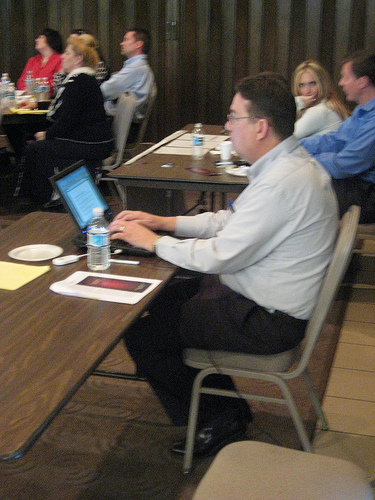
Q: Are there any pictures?
A: No, there are no pictures.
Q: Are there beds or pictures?
A: No, there are no pictures or beds.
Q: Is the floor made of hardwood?
A: Yes, the floor is made of hardwood.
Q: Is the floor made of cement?
A: No, the floor is made of hardwood.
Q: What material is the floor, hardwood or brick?
A: The floor is made of hardwood.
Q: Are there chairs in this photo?
A: Yes, there is a chair.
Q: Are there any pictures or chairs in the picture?
A: Yes, there is a chair.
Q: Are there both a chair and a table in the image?
A: Yes, there are both a chair and a table.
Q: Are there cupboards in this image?
A: No, there are no cupboards.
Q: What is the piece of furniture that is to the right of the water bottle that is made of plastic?
A: The piece of furniture is a chair.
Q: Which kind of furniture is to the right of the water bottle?
A: The piece of furniture is a chair.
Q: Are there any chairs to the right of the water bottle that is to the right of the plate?
A: Yes, there is a chair to the right of the water bottle.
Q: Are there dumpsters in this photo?
A: No, there are no dumpsters.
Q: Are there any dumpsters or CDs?
A: No, there are no dumpsters or cds.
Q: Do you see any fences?
A: No, there are no fences.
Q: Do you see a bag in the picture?
A: No, there are no bags.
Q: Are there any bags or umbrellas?
A: No, there are no bags or umbrellas.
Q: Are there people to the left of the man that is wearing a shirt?
A: Yes, there are people to the left of the man.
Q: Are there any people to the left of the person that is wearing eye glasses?
A: Yes, there are people to the left of the man.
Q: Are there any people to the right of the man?
A: No, the people are to the left of the man.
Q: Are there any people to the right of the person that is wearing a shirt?
A: No, the people are to the left of the man.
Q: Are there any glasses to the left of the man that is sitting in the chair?
A: No, there are people to the left of the man.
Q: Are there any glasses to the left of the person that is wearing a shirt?
A: No, there are people to the left of the man.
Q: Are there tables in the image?
A: Yes, there is a table.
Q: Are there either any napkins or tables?
A: Yes, there is a table.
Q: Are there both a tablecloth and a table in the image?
A: No, there is a table but no tablecloths.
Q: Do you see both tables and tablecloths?
A: No, there is a table but no tablecloths.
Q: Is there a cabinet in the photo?
A: No, there are no cabinets.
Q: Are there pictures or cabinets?
A: No, there are no cabinets or pictures.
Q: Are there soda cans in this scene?
A: No, there are no soda cans.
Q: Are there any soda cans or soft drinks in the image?
A: No, there are no soda cans or soft drinks.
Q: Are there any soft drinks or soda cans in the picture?
A: No, there are no soda cans or soft drinks.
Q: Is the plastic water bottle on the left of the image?
A: Yes, the water bottle is on the left of the image.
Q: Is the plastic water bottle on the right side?
A: No, the water bottle is on the left of the image.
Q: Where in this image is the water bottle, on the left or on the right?
A: The water bottle is on the left of the image.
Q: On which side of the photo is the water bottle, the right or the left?
A: The water bottle is on the left of the image.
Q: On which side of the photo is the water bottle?
A: The water bottle is on the left of the image.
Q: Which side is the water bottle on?
A: The water bottle is on the left of the image.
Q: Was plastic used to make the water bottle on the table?
A: Yes, the water bottle is made of plastic.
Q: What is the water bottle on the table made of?
A: The water bottle is made of plastic.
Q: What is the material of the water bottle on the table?
A: The water bottle is made of plastic.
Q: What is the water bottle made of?
A: The water bottle is made of plastic.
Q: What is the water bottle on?
A: The water bottle is on the table.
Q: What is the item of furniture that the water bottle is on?
A: The piece of furniture is a table.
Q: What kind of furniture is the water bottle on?
A: The water bottle is on the table.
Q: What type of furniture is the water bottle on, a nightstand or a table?
A: The water bottle is on a table.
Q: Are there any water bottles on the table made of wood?
A: Yes, there is a water bottle on the table.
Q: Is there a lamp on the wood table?
A: No, there is a water bottle on the table.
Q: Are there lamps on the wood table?
A: No, there is a water bottle on the table.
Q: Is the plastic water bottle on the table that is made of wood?
A: Yes, the water bottle is on the table.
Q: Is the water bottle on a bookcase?
A: No, the water bottle is on the table.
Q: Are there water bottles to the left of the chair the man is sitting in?
A: Yes, there is a water bottle to the left of the chair.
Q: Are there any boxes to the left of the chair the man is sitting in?
A: No, there is a water bottle to the left of the chair.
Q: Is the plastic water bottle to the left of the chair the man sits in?
A: Yes, the water bottle is to the left of the chair.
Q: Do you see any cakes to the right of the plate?
A: No, there is a water bottle to the right of the plate.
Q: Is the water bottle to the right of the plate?
A: Yes, the water bottle is to the right of the plate.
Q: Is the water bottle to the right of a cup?
A: No, the water bottle is to the right of the plate.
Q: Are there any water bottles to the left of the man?
A: Yes, there is a water bottle to the left of the man.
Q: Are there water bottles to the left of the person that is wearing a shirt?
A: Yes, there is a water bottle to the left of the man.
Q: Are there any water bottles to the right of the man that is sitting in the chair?
A: No, the water bottle is to the left of the man.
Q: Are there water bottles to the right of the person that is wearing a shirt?
A: No, the water bottle is to the left of the man.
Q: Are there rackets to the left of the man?
A: No, there is a water bottle to the left of the man.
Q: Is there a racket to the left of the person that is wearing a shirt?
A: No, there is a water bottle to the left of the man.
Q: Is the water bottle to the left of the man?
A: Yes, the water bottle is to the left of the man.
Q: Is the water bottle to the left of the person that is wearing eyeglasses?
A: Yes, the water bottle is to the left of the man.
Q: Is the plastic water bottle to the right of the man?
A: No, the water bottle is to the left of the man.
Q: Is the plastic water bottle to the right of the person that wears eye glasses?
A: No, the water bottle is to the left of the man.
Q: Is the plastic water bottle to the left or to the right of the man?
A: The water bottle is to the left of the man.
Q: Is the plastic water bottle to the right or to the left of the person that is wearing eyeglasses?
A: The water bottle is to the left of the man.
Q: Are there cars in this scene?
A: No, there are no cars.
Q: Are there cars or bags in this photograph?
A: No, there are no cars or bags.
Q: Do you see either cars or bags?
A: No, there are no cars or bags.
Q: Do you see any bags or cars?
A: No, there are no cars or bags.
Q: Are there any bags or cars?
A: No, there are no cars or bags.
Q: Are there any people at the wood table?
A: Yes, there are people at the table.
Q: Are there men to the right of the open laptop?
A: Yes, there is a man to the right of the laptop.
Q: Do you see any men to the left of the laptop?
A: No, the man is to the right of the laptop.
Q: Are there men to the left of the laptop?
A: No, the man is to the right of the laptop.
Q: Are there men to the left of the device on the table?
A: No, the man is to the right of the laptop.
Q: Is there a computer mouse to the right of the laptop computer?
A: No, there is a man to the right of the laptop computer.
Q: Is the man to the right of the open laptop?
A: Yes, the man is to the right of the laptop.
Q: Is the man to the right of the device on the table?
A: Yes, the man is to the right of the laptop.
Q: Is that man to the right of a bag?
A: No, the man is to the right of the laptop.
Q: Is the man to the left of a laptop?
A: No, the man is to the right of a laptop.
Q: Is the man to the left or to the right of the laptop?
A: The man is to the right of the laptop.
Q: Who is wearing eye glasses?
A: The man is wearing eye glasses.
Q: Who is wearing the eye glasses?
A: The man is wearing eye glasses.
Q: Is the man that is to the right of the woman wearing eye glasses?
A: Yes, the man is wearing eye glasses.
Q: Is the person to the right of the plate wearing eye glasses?
A: Yes, the man is wearing eye glasses.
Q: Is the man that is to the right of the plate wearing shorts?
A: No, the man is wearing eye glasses.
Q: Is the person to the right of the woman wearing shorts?
A: No, the man is wearing eye glasses.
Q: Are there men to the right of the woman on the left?
A: Yes, there is a man to the right of the woman.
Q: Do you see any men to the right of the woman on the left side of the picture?
A: Yes, there is a man to the right of the woman.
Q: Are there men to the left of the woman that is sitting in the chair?
A: No, the man is to the right of the woman.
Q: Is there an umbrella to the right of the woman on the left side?
A: No, there is a man to the right of the woman.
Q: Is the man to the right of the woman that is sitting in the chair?
A: Yes, the man is to the right of the woman.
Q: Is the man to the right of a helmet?
A: No, the man is to the right of the woman.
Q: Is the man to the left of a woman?
A: No, the man is to the right of a woman.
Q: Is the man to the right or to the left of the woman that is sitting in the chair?
A: The man is to the right of the woman.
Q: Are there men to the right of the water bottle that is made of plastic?
A: Yes, there is a man to the right of the water bottle.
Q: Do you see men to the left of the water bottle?
A: No, the man is to the right of the water bottle.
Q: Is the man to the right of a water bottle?
A: Yes, the man is to the right of a water bottle.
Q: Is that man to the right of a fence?
A: No, the man is to the right of a water bottle.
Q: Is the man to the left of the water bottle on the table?
A: No, the man is to the right of the water bottle.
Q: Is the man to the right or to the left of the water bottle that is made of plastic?
A: The man is to the right of the water bottle.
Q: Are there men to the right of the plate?
A: Yes, there is a man to the right of the plate.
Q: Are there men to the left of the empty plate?
A: No, the man is to the right of the plate.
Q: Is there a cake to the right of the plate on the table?
A: No, there is a man to the right of the plate.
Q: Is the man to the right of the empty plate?
A: Yes, the man is to the right of the plate.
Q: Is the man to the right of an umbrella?
A: No, the man is to the right of the plate.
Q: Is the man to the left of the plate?
A: No, the man is to the right of the plate.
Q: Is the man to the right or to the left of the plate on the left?
A: The man is to the right of the plate.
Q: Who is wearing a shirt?
A: The man is wearing a shirt.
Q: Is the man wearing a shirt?
A: Yes, the man is wearing a shirt.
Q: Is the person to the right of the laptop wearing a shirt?
A: Yes, the man is wearing a shirt.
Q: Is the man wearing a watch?
A: No, the man is wearing a shirt.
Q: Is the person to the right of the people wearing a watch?
A: No, the man is wearing a shirt.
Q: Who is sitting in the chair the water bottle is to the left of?
A: The man is sitting in the chair.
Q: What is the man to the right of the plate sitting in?
A: The man is sitting in the chair.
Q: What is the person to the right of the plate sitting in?
A: The man is sitting in the chair.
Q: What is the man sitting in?
A: The man is sitting in the chair.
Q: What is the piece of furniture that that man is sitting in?
A: The piece of furniture is a chair.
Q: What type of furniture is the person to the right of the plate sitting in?
A: The man is sitting in the chair.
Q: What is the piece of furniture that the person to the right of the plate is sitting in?
A: The piece of furniture is a chair.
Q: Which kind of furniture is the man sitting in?
A: The man is sitting in the chair.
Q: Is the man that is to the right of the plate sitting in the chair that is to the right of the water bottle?
A: Yes, the man is sitting in the chair.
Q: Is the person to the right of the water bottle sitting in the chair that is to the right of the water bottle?
A: Yes, the man is sitting in the chair.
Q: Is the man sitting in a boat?
A: No, the man is sitting in the chair.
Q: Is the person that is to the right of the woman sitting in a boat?
A: No, the man is sitting in the chair.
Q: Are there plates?
A: Yes, there is a plate.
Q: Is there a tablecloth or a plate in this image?
A: Yes, there is a plate.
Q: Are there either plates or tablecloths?
A: Yes, there is a plate.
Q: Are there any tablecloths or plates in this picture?
A: Yes, there is a plate.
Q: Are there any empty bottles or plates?
A: Yes, there is an empty plate.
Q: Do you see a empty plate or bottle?
A: Yes, there is an empty plate.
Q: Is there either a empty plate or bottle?
A: Yes, there is an empty plate.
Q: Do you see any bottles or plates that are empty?
A: Yes, the plate is empty.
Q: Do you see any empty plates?
A: Yes, there is an empty plate.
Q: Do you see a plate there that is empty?
A: Yes, there is a plate that is empty.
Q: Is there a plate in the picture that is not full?
A: Yes, there is a empty plate.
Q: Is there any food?
A: No, there is no food.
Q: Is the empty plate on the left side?
A: Yes, the plate is on the left of the image.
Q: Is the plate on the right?
A: No, the plate is on the left of the image.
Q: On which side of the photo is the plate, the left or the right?
A: The plate is on the left of the image.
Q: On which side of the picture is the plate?
A: The plate is on the left of the image.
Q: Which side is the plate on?
A: The plate is on the left of the image.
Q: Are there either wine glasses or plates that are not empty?
A: No, there is a plate but it is empty.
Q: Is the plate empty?
A: Yes, the plate is empty.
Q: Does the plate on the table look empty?
A: Yes, the plate is empty.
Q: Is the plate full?
A: No, the plate is empty.